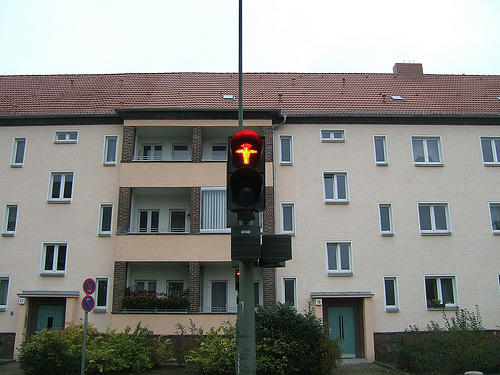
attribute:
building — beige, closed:
[0, 67, 497, 366]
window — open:
[423, 274, 463, 311]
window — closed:
[324, 236, 358, 276]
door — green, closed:
[324, 305, 358, 362]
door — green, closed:
[34, 302, 66, 362]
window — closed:
[323, 169, 351, 206]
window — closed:
[418, 203, 455, 239]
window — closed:
[411, 134, 445, 169]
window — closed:
[45, 168, 76, 204]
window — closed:
[39, 239, 70, 276]